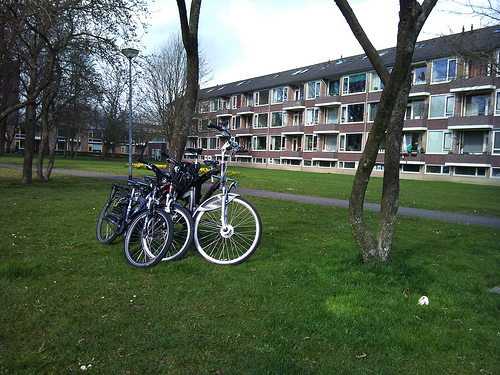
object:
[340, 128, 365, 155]
window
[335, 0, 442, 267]
trunk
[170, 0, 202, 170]
trunk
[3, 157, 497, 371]
grass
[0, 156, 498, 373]
lawn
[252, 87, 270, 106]
window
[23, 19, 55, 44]
branches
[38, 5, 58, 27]
branches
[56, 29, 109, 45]
branches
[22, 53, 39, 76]
branches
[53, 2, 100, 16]
branches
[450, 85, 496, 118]
window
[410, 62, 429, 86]
window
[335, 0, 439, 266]
tree trunk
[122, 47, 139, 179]
chili pepper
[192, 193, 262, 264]
tire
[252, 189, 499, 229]
cement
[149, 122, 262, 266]
bikes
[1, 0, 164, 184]
tree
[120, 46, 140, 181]
street lamp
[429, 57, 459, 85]
window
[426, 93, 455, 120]
window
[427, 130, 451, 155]
window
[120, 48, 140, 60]
light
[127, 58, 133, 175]
pole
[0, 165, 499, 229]
asphalt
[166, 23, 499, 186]
building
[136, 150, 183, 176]
handle bars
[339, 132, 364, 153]
window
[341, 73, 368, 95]
window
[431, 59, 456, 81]
window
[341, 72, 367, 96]
building window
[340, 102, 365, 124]
building window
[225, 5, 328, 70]
cloudy sky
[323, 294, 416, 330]
patch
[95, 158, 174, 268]
bike